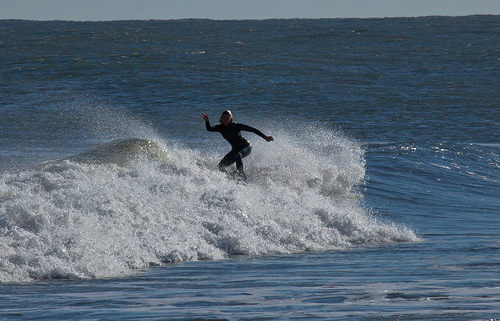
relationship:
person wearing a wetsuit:
[199, 108, 275, 183] [201, 122, 266, 173]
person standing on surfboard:
[199, 108, 275, 183] [223, 170, 248, 183]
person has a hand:
[199, 108, 275, 183] [201, 111, 211, 121]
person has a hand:
[199, 108, 275, 183] [264, 135, 275, 143]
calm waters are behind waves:
[0, 36, 495, 115] [1, 132, 498, 278]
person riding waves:
[199, 108, 275, 183] [1, 132, 498, 278]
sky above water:
[1, 0, 500, 17] [0, 16, 499, 319]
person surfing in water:
[199, 108, 275, 183] [0, 16, 499, 319]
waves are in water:
[1, 132, 498, 278] [0, 16, 499, 319]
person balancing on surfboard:
[199, 108, 275, 183] [223, 170, 248, 183]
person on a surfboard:
[199, 108, 275, 183] [223, 170, 248, 183]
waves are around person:
[1, 132, 498, 278] [199, 108, 275, 183]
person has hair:
[199, 108, 275, 183] [216, 111, 236, 123]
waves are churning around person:
[1, 132, 498, 278] [199, 108, 275, 183]